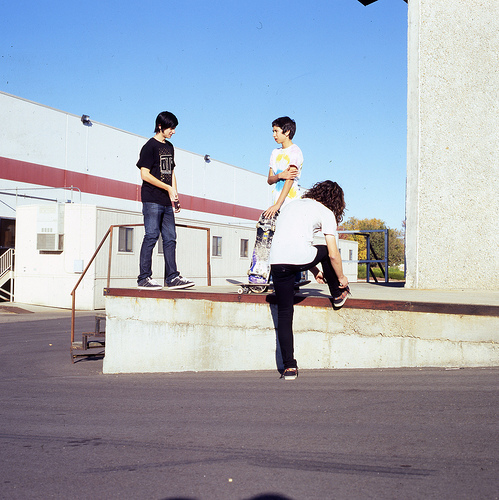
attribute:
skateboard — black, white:
[220, 272, 328, 302]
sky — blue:
[6, 5, 408, 135]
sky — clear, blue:
[163, 35, 367, 103]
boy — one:
[263, 115, 303, 190]